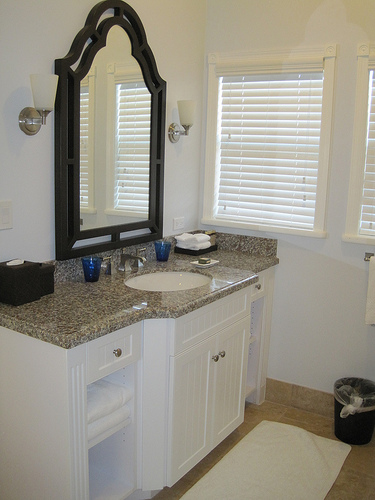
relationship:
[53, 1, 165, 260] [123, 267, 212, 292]
mirror above sink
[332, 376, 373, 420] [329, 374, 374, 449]
clear bag inside wastebasket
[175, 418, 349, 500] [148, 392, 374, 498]
mat on top floor